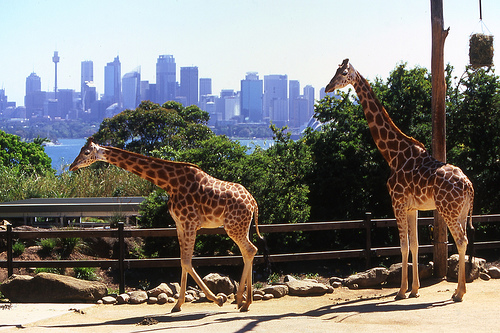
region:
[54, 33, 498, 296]
two giraffes in the fence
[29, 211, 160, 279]
the fence is brown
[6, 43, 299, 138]
the buildings are by the river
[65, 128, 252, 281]
the giraffe is brown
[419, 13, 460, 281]
the pole is brown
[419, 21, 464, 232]
the pole is made of wood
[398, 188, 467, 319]
the giraffe has four feet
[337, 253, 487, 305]
the rocks are brown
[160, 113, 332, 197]
the bushes is green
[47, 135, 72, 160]
the water is blue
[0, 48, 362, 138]
City seen behind the Giraffes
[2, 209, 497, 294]
The wood fence behind the giraffes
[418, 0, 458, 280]
Tree trunk behind the giraffe on the right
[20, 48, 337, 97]
Skyline of the city behind the giraffes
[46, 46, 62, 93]
Tallest building shown in the city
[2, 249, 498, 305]
Rocks at the bottom of the wood fence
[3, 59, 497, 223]
Trees behind the giraffes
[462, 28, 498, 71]
Feeder hanging behind the animals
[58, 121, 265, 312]
Giraffe with its head lowered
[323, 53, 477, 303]
Taller of the two giraffes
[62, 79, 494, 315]
Two giraffes in a zoo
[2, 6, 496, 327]
Day is sunny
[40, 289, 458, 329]
Giraffe shadows casting on the soil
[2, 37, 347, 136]
Tall buildings in the city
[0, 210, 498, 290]
Fence surround giraffes pen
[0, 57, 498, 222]
Green trees in the zoo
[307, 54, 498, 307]
Big giraffes behind a small one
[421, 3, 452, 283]
Wood pole in the pen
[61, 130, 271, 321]
Small giraffe with low neck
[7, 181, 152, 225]
Open building with black roof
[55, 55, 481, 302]
these are two giraffes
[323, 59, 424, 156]
this giraffe has tall neck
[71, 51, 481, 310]
the giraffes are brown and white in color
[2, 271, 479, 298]
the rocks are along the path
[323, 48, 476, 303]
this giraffe is taller than the other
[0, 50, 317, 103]
the buildings are on the farthest part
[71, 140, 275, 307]
this giraffe is walking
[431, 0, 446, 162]
a wooden pole is beside the giraffe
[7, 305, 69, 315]
the sun is shining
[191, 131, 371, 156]
the trees are opposite the giraffes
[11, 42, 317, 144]
city skyline in the distance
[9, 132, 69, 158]
boat on the water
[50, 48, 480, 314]
a pair of giraffes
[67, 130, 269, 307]
brown and tan giraffe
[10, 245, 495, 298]
rocks at edge of enclosure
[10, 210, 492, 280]
low brown wooden fence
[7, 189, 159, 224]
grey metal tracks in the shrubs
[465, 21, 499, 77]
hay bale hanging from post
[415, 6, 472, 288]
tall brown wooden post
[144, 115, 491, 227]
leafy green shrubs behind fence